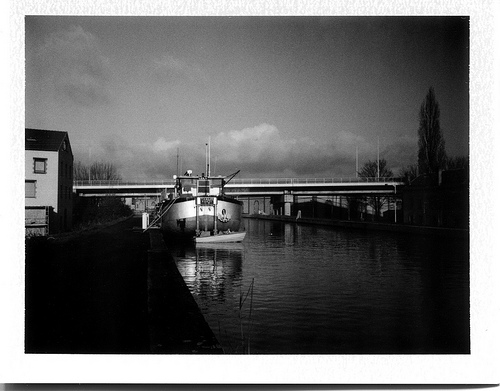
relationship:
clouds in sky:
[130, 123, 417, 187] [26, 12, 465, 181]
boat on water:
[158, 135, 243, 240] [142, 200, 468, 351]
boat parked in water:
[155, 129, 249, 263] [142, 200, 468, 351]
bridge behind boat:
[129, 122, 444, 230] [139, 134, 246, 254]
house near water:
[21, 128, 73, 243] [130, 213, 471, 353]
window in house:
[33, 157, 45, 172] [23, 125, 74, 234]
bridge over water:
[72, 175, 411, 227] [142, 200, 468, 351]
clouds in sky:
[134, 119, 415, 180] [26, 12, 465, 181]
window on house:
[33, 157, 45, 172] [24, 127, 74, 212]